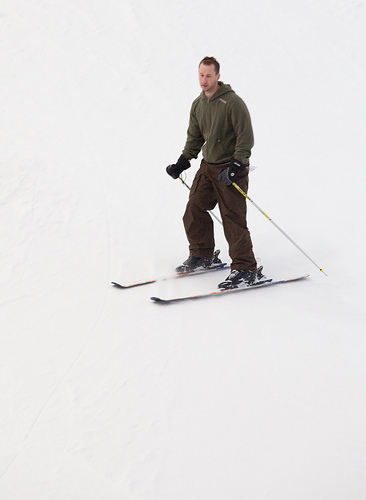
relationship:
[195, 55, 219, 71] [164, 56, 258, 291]
hair belonging to man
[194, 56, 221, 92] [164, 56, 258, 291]
head belonging to man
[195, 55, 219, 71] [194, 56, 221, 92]
hair growing on head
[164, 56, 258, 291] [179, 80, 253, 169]
man wearing man sweatshirt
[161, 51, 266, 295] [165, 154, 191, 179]
man wearing glove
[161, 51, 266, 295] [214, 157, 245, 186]
man wearing glove